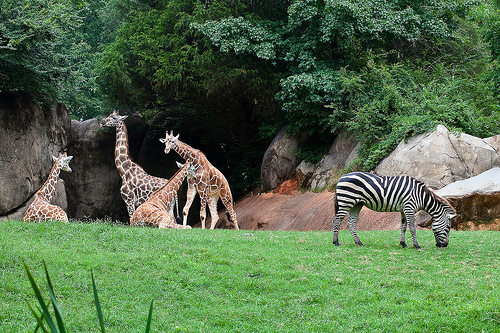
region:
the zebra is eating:
[319, 161, 484, 263]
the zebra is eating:
[330, 174, 447, 331]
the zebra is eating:
[332, 117, 492, 237]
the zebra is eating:
[310, 163, 400, 293]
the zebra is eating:
[300, 113, 407, 243]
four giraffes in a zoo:
[16, 101, 248, 234]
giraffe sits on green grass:
[25, 135, 87, 232]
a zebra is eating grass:
[328, 162, 465, 255]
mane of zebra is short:
[418, 170, 463, 214]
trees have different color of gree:
[7, 2, 497, 122]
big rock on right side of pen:
[367, 113, 497, 177]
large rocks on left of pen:
[0, 69, 113, 218]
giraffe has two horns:
[153, 122, 194, 160]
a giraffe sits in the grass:
[127, 150, 211, 241]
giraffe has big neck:
[91, 105, 155, 179]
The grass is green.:
[191, 250, 313, 326]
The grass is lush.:
[178, 250, 314, 331]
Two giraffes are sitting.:
[17, 147, 199, 241]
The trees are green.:
[44, 5, 400, 105]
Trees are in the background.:
[46, 0, 404, 85]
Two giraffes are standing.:
[92, 102, 244, 232]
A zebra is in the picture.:
[317, 167, 460, 258]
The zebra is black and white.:
[320, 167, 458, 259]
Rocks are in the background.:
[227, 132, 492, 229]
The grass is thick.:
[191, 254, 335, 325]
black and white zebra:
[328, 168, 455, 252]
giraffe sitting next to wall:
[23, 148, 73, 225]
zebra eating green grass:
[328, 167, 460, 254]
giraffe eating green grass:
[129, 156, 196, 235]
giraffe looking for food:
[98, 109, 175, 224]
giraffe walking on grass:
[162, 129, 240, 230]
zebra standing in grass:
[330, 168, 458, 250]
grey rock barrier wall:
[2, 93, 178, 220]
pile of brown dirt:
[228, 188, 408, 231]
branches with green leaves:
[193, 3, 453, 65]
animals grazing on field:
[44, 48, 495, 308]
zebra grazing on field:
[300, 151, 464, 273]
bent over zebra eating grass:
[304, 120, 478, 317]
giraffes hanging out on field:
[12, 92, 222, 272]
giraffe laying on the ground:
[128, 151, 208, 235]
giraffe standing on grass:
[145, 115, 252, 220]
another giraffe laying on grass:
[28, 142, 72, 239]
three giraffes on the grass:
[92, 80, 236, 262]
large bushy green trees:
[8, 11, 398, 106]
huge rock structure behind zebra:
[207, 100, 484, 232]